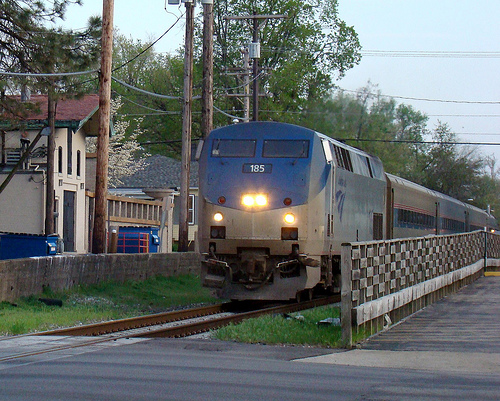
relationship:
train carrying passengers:
[210, 122, 497, 248] [321, 147, 468, 222]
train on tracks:
[210, 122, 497, 248] [46, 313, 349, 341]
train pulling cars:
[208, 121, 418, 190] [391, 172, 499, 250]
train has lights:
[208, 121, 418, 190] [227, 175, 273, 190]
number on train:
[247, 159, 279, 176] [208, 121, 418, 190]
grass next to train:
[17, 302, 343, 350] [208, 121, 418, 190]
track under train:
[79, 306, 260, 338] [208, 121, 418, 190]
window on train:
[265, 137, 315, 160] [208, 121, 418, 190]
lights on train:
[227, 175, 273, 190] [208, 121, 418, 190]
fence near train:
[349, 222, 499, 296] [208, 121, 418, 190]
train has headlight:
[208, 121, 418, 190] [216, 179, 308, 220]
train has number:
[208, 121, 418, 190] [247, 159, 279, 176]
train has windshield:
[208, 121, 418, 190] [216, 138, 310, 158]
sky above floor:
[131, 4, 496, 89] [0, 271, 500, 400]